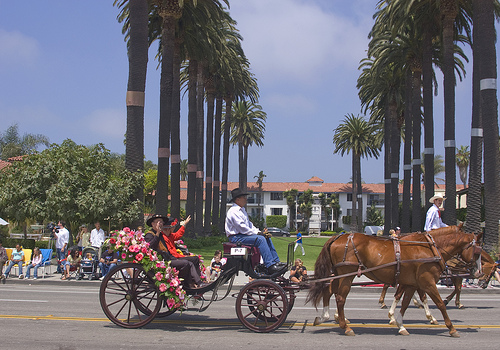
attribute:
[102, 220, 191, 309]
roses — pink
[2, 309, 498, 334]
lines — yellow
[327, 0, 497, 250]
trees — tall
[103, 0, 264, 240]
trees — tall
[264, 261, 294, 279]
shoes — black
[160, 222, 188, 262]
jacket — red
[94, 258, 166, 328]
wheel — large, brown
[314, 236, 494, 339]
horse — brown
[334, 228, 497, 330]
horse — brown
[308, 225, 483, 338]
horse — brown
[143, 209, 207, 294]
man — waving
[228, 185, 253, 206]
hat — black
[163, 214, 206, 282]
person — waving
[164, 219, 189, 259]
clothes — red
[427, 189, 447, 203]
hat — white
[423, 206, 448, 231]
shirt — white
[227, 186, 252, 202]
hat — black, cowboy style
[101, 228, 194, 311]
flowers — pink, red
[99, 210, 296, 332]
carriage — one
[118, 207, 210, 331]
chair — yellow